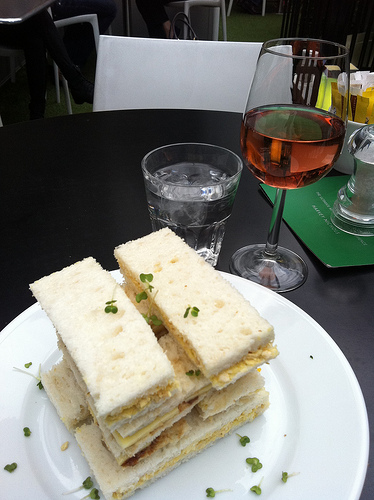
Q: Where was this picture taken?
A: A cafe.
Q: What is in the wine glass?
A: Wine.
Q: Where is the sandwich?
A: A plate.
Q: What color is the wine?
A: Rose.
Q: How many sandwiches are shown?
A: Six.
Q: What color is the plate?
A: White.